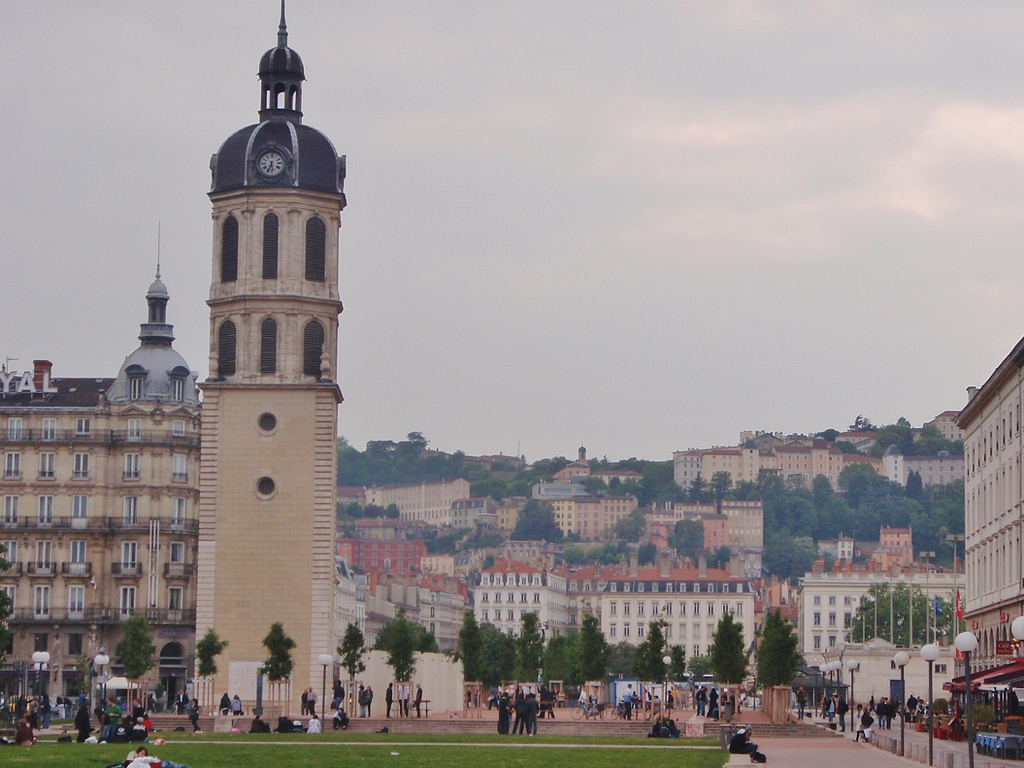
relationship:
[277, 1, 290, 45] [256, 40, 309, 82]
spire topping dome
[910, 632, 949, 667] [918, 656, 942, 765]
globe on utility pole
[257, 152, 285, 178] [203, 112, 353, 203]
clock on dome roof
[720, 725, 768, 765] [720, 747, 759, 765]
person sits on curb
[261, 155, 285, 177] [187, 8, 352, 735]
clock on top of building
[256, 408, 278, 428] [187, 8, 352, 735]
circle on building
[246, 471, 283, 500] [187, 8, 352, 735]
circle on building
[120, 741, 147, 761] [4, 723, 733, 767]
person sitting on grass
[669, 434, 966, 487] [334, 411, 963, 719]
buildings on city hill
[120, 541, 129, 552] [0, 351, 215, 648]
window on building